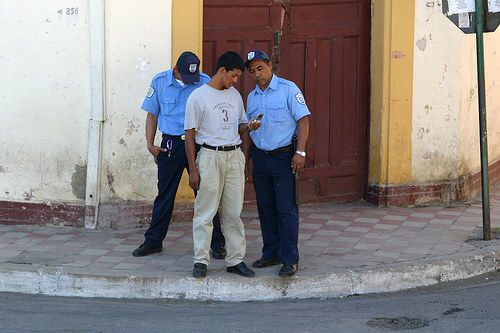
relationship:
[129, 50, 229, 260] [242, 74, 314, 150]
man wearing shirt